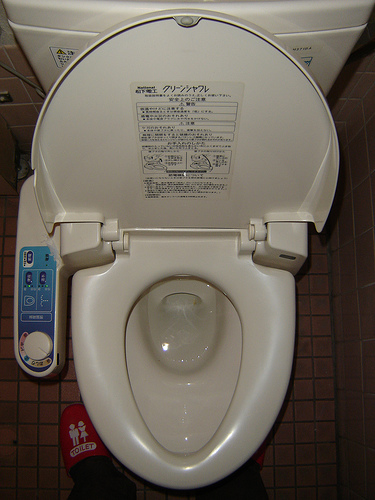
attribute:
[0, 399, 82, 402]
grout line — Small , brown, of grout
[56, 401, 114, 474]
slipper — Red 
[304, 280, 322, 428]
line — Small, brown, of grout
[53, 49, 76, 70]
sticker — warning, toilet's 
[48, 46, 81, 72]
label — warning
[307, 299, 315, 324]
grout line — of grout, brown, Small 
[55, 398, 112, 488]
cup — red 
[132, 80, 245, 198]
sticker — white, instructions 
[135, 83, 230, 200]
text — black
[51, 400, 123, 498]
shoe — red, white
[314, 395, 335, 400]
grout — Small, brown , line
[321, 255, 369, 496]
line — Small, brown, of grout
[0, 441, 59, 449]
line — of grout, brown, Small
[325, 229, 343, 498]
grout line — Small , brown , of grout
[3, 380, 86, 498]
floor — brown 